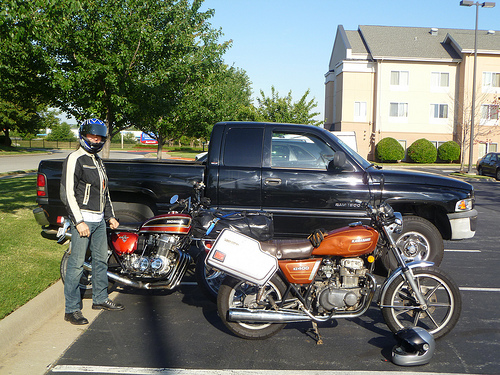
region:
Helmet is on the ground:
[387, 317, 437, 367]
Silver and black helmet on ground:
[385, 321, 435, 361]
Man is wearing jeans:
[65, 216, 112, 313]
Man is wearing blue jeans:
[60, 216, 113, 317]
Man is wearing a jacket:
[55, 145, 117, 227]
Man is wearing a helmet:
[74, 114, 109, 154]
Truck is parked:
[35, 116, 478, 283]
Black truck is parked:
[33, 117, 483, 277]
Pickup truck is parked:
[30, 115, 477, 277]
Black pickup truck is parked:
[32, 117, 478, 272]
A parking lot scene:
[0, 0, 498, 372]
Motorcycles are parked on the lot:
[57, 169, 462, 341]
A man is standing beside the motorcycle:
[54, 117, 126, 325]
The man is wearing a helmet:
[74, 115, 111, 154]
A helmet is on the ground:
[388, 323, 435, 365]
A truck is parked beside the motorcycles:
[30, 116, 477, 339]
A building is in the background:
[322, 22, 498, 166]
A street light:
[456, 0, 498, 177]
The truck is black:
[31, 119, 480, 268]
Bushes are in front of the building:
[371, 132, 461, 164]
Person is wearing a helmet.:
[77, 117, 111, 158]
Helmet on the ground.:
[369, 328, 439, 368]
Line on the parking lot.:
[424, 278, 499, 307]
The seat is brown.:
[259, 239, 332, 270]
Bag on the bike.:
[205, 216, 291, 247]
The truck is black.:
[102, 171, 232, 207]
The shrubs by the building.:
[368, 129, 475, 168]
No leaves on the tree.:
[456, 93, 499, 140]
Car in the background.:
[114, 119, 186, 152]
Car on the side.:
[469, 148, 499, 202]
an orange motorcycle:
[206, 196, 461, 343]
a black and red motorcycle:
[59, 180, 254, 300]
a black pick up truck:
[32, 116, 478, 277]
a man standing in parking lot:
[59, 117, 128, 323]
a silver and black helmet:
[389, 322, 433, 365]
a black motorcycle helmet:
[76, 114, 106, 151]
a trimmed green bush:
[373, 134, 404, 163]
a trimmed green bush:
[406, 138, 437, 164]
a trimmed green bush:
[434, 138, 460, 163]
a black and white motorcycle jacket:
[60, 147, 114, 224]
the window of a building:
[385, 65, 417, 88]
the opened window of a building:
[426, 100, 450, 120]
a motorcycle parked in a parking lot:
[206, 191, 462, 343]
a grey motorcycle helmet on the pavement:
[386, 320, 440, 372]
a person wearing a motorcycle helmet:
[58, 111, 121, 331]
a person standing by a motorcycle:
[52, 121, 188, 327]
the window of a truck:
[266, 123, 351, 174]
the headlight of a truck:
[452, 196, 474, 218]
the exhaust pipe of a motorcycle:
[226, 302, 345, 329]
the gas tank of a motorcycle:
[309, 222, 384, 259]